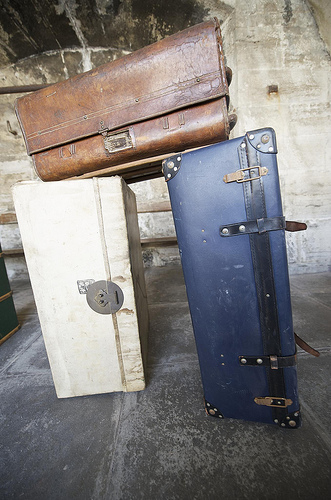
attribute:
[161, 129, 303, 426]
suitcase — blue, leather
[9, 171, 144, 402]
suitcase — white, scuffed, tan, green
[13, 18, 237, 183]
suitcase — brown, balancing, leather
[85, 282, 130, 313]
clasp — round, metal